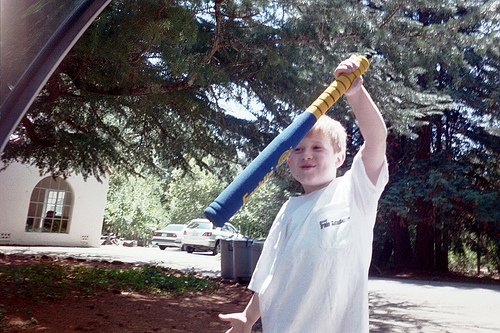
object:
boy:
[247, 54, 392, 333]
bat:
[204, 54, 371, 227]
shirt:
[247, 141, 392, 333]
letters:
[319, 219, 345, 230]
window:
[24, 176, 77, 235]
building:
[0, 137, 111, 249]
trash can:
[219, 238, 233, 279]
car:
[181, 218, 242, 256]